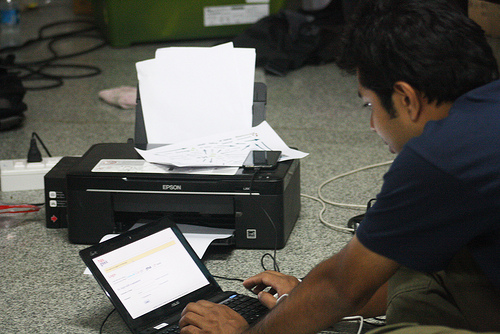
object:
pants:
[385, 266, 500, 334]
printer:
[43, 82, 301, 249]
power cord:
[27, 130, 52, 162]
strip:
[2, 205, 39, 213]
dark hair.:
[336, 0, 500, 118]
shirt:
[355, 77, 500, 289]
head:
[333, 0, 500, 153]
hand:
[241, 269, 301, 308]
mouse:
[243, 273, 277, 297]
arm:
[179, 136, 455, 333]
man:
[176, 8, 500, 334]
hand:
[178, 300, 251, 334]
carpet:
[0, 231, 40, 318]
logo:
[162, 184, 181, 190]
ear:
[394, 79, 421, 122]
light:
[50, 215, 59, 222]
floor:
[43, 245, 80, 300]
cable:
[300, 193, 355, 234]